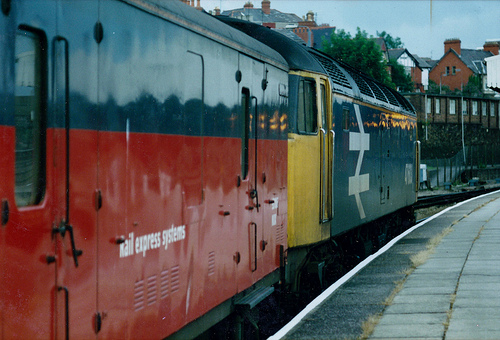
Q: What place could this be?
A: It is a station.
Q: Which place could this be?
A: It is a station.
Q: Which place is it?
A: It is a station.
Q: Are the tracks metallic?
A: Yes, the tracks are metallic.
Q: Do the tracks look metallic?
A: Yes, the tracks are metallic.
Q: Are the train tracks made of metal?
A: Yes, the train tracks are made of metal.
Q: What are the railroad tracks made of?
A: The railroad tracks are made of metal.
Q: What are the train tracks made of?
A: The railroad tracks are made of metal.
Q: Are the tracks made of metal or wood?
A: The tracks are made of metal.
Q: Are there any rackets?
A: No, there are no rackets.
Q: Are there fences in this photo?
A: Yes, there is a fence.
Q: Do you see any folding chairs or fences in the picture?
A: Yes, there is a fence.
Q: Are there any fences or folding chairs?
A: Yes, there is a fence.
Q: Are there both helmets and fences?
A: No, there is a fence but no helmets.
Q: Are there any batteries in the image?
A: No, there are no batteries.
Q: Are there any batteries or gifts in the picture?
A: No, there are no batteries or gifts.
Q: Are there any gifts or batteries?
A: No, there are no batteries or gifts.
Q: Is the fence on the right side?
A: Yes, the fence is on the right of the image.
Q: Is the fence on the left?
A: No, the fence is on the right of the image.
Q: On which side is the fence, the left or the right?
A: The fence is on the right of the image.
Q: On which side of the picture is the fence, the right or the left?
A: The fence is on the right of the image.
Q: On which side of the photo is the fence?
A: The fence is on the right of the image.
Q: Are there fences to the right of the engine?
A: Yes, there is a fence to the right of the engine.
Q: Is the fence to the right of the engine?
A: Yes, the fence is to the right of the engine.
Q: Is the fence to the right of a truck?
A: No, the fence is to the right of the engine.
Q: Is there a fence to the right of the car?
A: Yes, there is a fence to the right of the car.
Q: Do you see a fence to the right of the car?
A: Yes, there is a fence to the right of the car.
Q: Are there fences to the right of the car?
A: Yes, there is a fence to the right of the car.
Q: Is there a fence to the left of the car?
A: No, the fence is to the right of the car.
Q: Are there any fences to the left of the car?
A: No, the fence is to the right of the car.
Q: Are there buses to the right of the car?
A: No, there is a fence to the right of the car.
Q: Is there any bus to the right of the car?
A: No, there is a fence to the right of the car.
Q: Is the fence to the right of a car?
A: Yes, the fence is to the right of a car.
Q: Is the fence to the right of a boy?
A: No, the fence is to the right of a car.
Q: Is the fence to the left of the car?
A: No, the fence is to the right of the car.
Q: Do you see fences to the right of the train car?
A: Yes, there is a fence to the right of the train car.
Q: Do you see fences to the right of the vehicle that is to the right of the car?
A: Yes, there is a fence to the right of the train car.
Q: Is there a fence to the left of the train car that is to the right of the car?
A: No, the fence is to the right of the train car.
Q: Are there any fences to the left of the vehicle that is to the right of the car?
A: No, the fence is to the right of the train car.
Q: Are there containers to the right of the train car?
A: No, there is a fence to the right of the train car.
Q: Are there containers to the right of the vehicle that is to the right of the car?
A: No, there is a fence to the right of the train car.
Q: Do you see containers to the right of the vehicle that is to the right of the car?
A: No, there is a fence to the right of the train car.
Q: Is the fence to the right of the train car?
A: Yes, the fence is to the right of the train car.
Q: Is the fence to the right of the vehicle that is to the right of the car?
A: Yes, the fence is to the right of the train car.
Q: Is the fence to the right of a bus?
A: No, the fence is to the right of the train car.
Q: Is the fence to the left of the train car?
A: No, the fence is to the right of the train car.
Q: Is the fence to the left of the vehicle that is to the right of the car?
A: No, the fence is to the right of the train car.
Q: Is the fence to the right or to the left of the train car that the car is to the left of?
A: The fence is to the right of the train car.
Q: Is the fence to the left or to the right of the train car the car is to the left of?
A: The fence is to the right of the train car.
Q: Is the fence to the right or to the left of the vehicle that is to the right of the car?
A: The fence is to the right of the train car.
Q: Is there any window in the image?
A: Yes, there is a window.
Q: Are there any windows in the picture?
A: Yes, there is a window.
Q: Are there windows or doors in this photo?
A: Yes, there is a window.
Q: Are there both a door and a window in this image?
A: Yes, there are both a window and a door.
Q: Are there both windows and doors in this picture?
A: Yes, there are both a window and a door.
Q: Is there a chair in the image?
A: No, there are no chairs.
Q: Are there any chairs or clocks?
A: No, there are no chairs or clocks.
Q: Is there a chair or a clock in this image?
A: No, there are no chairs or clocks.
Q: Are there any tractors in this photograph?
A: No, there are no tractors.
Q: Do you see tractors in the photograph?
A: No, there are no tractors.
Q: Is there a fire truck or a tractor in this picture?
A: No, there are no tractors or fire trucks.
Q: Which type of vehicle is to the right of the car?
A: The vehicle is a train car.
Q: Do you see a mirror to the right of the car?
A: No, there is a train car to the right of the car.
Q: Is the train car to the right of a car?
A: Yes, the train car is to the right of a car.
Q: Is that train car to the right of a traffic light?
A: No, the train car is to the right of a car.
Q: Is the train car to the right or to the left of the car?
A: The train car is to the right of the car.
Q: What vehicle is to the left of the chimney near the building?
A: The vehicle is a train car.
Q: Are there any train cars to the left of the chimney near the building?
A: Yes, there is a train car to the left of the chimney.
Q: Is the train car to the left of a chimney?
A: Yes, the train car is to the left of a chimney.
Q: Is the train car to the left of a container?
A: No, the train car is to the left of a chimney.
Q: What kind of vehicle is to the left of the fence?
A: The vehicle is a train car.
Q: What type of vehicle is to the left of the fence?
A: The vehicle is a train car.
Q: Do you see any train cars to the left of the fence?
A: Yes, there is a train car to the left of the fence.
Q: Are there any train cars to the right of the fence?
A: No, the train car is to the left of the fence.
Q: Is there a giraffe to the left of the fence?
A: No, there is a train car to the left of the fence.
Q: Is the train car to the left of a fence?
A: Yes, the train car is to the left of a fence.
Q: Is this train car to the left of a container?
A: No, the train car is to the left of a fence.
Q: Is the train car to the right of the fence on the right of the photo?
A: No, the train car is to the left of the fence.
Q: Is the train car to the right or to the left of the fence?
A: The train car is to the left of the fence.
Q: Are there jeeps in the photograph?
A: No, there are no jeeps.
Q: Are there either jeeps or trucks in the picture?
A: No, there are no jeeps or trucks.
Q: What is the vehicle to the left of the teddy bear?
A: The vehicle is a car.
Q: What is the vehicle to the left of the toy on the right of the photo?
A: The vehicle is a car.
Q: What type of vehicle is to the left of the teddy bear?
A: The vehicle is a car.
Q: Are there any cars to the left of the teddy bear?
A: Yes, there is a car to the left of the teddy bear.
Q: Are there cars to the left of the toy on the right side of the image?
A: Yes, there is a car to the left of the teddy bear.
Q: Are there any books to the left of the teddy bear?
A: No, there is a car to the left of the teddy bear.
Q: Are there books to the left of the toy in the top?
A: No, there is a car to the left of the teddy bear.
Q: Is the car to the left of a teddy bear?
A: Yes, the car is to the left of a teddy bear.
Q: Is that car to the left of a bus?
A: No, the car is to the left of a teddy bear.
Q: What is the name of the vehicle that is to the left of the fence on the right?
A: The vehicle is a car.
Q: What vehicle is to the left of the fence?
A: The vehicle is a car.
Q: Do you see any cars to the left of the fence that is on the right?
A: Yes, there is a car to the left of the fence.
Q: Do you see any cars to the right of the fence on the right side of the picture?
A: No, the car is to the left of the fence.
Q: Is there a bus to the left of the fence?
A: No, there is a car to the left of the fence.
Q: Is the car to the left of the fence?
A: Yes, the car is to the left of the fence.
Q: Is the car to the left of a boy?
A: No, the car is to the left of the fence.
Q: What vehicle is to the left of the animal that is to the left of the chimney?
A: The vehicle is a car.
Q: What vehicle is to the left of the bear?
A: The vehicle is a car.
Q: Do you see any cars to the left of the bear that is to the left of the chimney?
A: Yes, there is a car to the left of the bear.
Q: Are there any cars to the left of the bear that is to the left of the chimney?
A: Yes, there is a car to the left of the bear.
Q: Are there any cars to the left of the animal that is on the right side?
A: Yes, there is a car to the left of the bear.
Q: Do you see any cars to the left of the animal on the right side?
A: Yes, there is a car to the left of the bear.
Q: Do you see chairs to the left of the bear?
A: No, there is a car to the left of the bear.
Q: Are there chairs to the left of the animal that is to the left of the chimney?
A: No, there is a car to the left of the bear.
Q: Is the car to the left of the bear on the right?
A: Yes, the car is to the left of the bear.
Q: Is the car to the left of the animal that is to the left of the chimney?
A: Yes, the car is to the left of the bear.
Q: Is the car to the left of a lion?
A: No, the car is to the left of the bear.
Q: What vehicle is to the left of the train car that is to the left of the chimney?
A: The vehicle is a car.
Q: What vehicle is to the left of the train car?
A: The vehicle is a car.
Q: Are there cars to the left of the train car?
A: Yes, there is a car to the left of the train car.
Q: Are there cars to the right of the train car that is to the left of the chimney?
A: No, the car is to the left of the train car.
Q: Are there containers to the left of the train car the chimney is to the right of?
A: No, there is a car to the left of the train car.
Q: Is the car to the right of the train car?
A: No, the car is to the left of the train car.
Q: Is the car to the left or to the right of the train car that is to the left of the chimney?
A: The car is to the left of the train car.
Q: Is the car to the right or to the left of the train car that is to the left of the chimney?
A: The car is to the left of the train car.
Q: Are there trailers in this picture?
A: No, there are no trailers.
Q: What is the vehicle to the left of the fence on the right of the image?
A: The vehicle is a locomotive.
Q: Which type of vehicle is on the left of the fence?
A: The vehicle is a locomotive.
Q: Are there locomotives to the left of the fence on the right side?
A: Yes, there is a locomotive to the left of the fence.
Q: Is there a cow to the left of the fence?
A: No, there is a locomotive to the left of the fence.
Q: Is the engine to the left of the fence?
A: Yes, the engine is to the left of the fence.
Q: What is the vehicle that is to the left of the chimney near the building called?
A: The vehicle is a locomotive.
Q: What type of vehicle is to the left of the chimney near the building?
A: The vehicle is a locomotive.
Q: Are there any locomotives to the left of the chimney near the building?
A: Yes, there is a locomotive to the left of the chimney.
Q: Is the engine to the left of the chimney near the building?
A: Yes, the engine is to the left of the chimney.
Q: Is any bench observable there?
A: No, there are no benches.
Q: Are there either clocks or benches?
A: No, there are no benches or clocks.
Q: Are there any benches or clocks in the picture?
A: No, there are no benches or clocks.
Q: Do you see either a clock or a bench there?
A: No, there are no benches or clocks.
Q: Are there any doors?
A: Yes, there is a door.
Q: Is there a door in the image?
A: Yes, there is a door.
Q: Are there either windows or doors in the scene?
A: Yes, there is a door.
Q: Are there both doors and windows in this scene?
A: Yes, there are both a door and windows.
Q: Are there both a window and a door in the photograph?
A: Yes, there are both a door and a window.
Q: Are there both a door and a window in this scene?
A: Yes, there are both a door and a window.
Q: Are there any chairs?
A: No, there are no chairs.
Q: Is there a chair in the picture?
A: No, there are no chairs.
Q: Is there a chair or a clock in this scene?
A: No, there are no chairs or clocks.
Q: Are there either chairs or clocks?
A: No, there are no chairs or clocks.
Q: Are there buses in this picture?
A: No, there are no buses.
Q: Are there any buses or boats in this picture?
A: No, there are no buses or boats.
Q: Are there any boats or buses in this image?
A: No, there are no buses or boats.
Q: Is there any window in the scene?
A: Yes, there is a window.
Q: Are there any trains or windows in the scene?
A: Yes, there is a window.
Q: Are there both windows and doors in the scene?
A: Yes, there are both a window and doors.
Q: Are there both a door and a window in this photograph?
A: Yes, there are both a window and a door.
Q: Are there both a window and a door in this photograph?
A: Yes, there are both a window and a door.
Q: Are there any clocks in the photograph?
A: No, there are no clocks.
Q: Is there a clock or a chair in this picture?
A: No, there are no clocks or chairs.